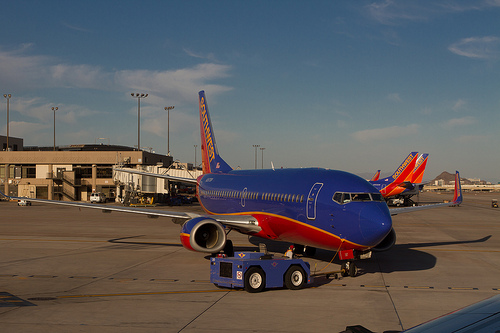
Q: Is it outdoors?
A: Yes, it is outdoors.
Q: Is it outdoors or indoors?
A: It is outdoors.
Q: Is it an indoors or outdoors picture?
A: It is outdoors.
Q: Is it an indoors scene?
A: No, it is outdoors.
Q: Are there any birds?
A: No, there are no birds.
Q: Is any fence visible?
A: No, there are no fences.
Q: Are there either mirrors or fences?
A: No, there are no fences or mirrors.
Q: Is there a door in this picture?
A: Yes, there is a door.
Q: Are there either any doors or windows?
A: Yes, there is a door.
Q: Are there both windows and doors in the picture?
A: Yes, there are both a door and windows.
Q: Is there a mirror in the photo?
A: No, there are no mirrors.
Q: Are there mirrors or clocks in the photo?
A: No, there are no mirrors or clocks.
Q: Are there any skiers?
A: No, there are no skiers.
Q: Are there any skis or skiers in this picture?
A: No, there are no skiers or skis.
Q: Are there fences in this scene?
A: No, there are no fences.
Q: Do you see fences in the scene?
A: No, there are no fences.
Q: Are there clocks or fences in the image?
A: No, there are no fences or clocks.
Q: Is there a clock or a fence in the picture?
A: No, there are no fences or clocks.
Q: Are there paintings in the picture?
A: No, there are no paintings.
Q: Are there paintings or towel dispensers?
A: No, there are no paintings or towel dispensers.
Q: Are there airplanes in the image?
A: Yes, there is an airplane.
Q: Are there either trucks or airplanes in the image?
A: Yes, there is an airplane.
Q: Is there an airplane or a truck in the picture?
A: Yes, there is an airplane.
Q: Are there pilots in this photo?
A: No, there are no pilots.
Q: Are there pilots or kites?
A: No, there are no pilots or kites.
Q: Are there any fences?
A: No, there are no fences.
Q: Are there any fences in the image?
A: No, there are no fences.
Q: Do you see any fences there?
A: No, there are no fences.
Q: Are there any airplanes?
A: Yes, there is an airplane.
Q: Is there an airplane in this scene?
A: Yes, there is an airplane.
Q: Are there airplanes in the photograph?
A: Yes, there is an airplane.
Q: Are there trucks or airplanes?
A: Yes, there is an airplane.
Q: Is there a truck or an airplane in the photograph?
A: Yes, there is an airplane.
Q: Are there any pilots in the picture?
A: No, there are no pilots.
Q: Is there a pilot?
A: No, there are no pilots.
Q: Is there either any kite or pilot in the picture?
A: No, there are no pilots or kites.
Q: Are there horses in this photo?
A: No, there are no horses.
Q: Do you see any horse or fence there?
A: No, there are no horses or fences.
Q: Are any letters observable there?
A: Yes, there are letters.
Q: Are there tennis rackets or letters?
A: Yes, there are letters.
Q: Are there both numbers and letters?
A: No, there are letters but no numbers.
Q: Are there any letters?
A: Yes, there are letters.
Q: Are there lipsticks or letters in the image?
A: Yes, there are letters.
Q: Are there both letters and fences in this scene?
A: No, there are letters but no fences.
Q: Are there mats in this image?
A: No, there are no mats.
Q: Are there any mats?
A: No, there are no mats.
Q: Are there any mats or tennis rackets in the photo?
A: No, there are no mats or tennis rackets.